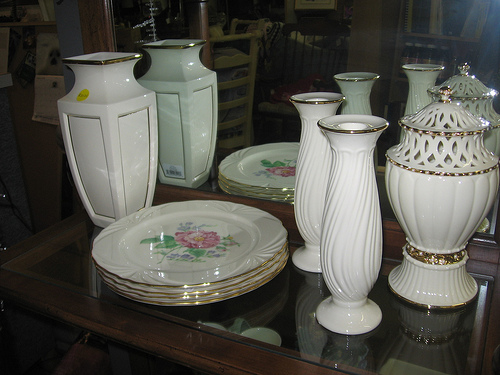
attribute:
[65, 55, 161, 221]
vase — white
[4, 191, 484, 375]
table — glass, brown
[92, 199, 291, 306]
plates — white, china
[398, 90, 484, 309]
vase — white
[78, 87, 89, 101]
sticker — yellow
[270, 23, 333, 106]
chair — tan, brown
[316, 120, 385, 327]
vase — white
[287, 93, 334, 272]
vase — white